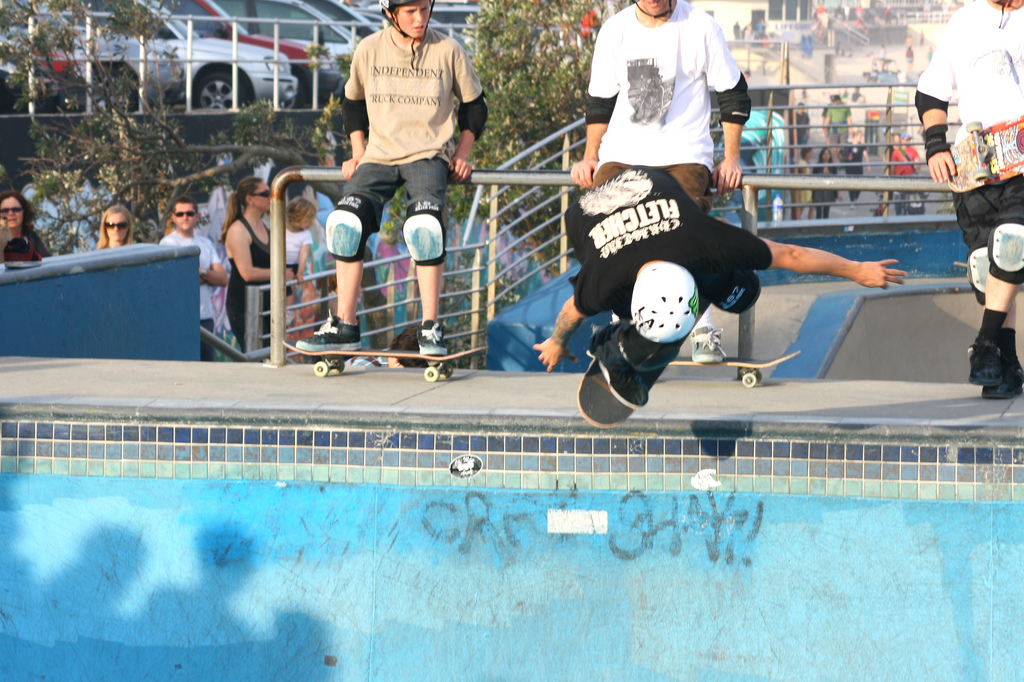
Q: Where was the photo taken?
A: At a skate park.